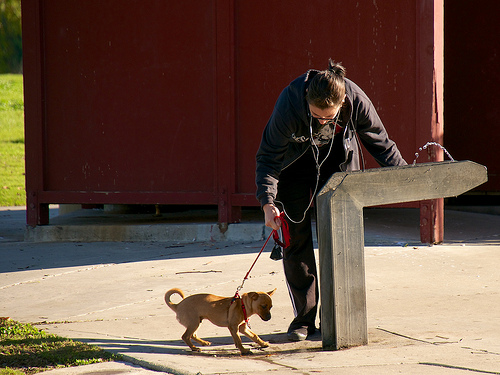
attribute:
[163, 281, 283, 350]
dog — brown 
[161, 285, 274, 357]
dog — brown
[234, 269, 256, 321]
harness — red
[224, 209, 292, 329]
leash — red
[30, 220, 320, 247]
foundation — cement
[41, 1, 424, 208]
wall — red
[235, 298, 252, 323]
collar — red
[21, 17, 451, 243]
building — large, red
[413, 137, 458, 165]
fountain — steel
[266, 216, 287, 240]
tie — red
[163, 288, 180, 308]
tail — cuved, brown